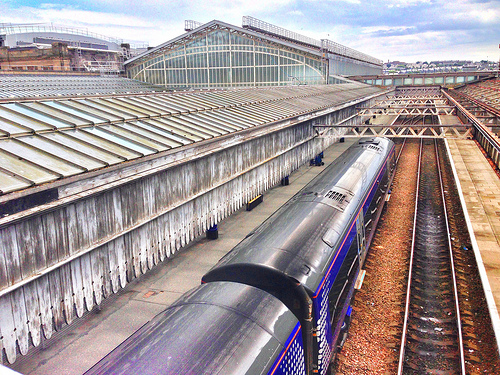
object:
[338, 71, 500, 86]
bridge walkway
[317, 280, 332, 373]
pattern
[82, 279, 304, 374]
metal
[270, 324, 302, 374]
pink stripe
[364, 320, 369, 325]
gravel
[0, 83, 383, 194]
metal roof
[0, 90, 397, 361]
wooden fence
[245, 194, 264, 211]
bench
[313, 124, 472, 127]
beam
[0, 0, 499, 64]
blue sky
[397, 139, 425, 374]
track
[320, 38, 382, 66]
fence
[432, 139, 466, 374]
tracks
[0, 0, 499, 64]
clouds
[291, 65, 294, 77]
glass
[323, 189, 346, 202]
vent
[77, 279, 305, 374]
car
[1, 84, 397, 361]
building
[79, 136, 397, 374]
train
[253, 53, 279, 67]
window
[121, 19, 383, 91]
building